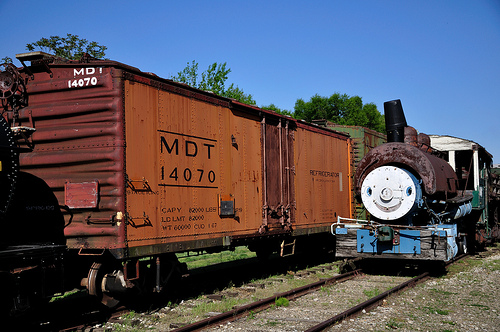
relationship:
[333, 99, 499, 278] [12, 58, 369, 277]
train beside train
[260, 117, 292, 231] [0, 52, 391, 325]
door on train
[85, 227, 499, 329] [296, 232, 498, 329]
gravel beside track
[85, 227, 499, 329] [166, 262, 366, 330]
gravel beside track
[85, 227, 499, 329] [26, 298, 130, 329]
gravel beside track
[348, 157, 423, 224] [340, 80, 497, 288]
face on train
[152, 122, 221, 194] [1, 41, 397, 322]
writing on train car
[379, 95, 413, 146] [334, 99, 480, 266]
smokestack on train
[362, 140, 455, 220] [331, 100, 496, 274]
head of train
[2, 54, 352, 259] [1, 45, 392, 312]
compartment of train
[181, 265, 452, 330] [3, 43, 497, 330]
rails of railway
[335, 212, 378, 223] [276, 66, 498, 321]
metal bar on train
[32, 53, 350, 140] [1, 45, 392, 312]
top of train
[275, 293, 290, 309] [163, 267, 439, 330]
grass on rail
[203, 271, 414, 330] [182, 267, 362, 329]
pebbles between rail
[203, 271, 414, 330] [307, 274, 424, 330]
pebbles between rail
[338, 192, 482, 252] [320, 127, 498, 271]
blue paint on train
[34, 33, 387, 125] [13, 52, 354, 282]
trees behind train car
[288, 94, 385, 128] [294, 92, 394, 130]
leaves on tree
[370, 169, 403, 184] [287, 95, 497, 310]
paint on front of train